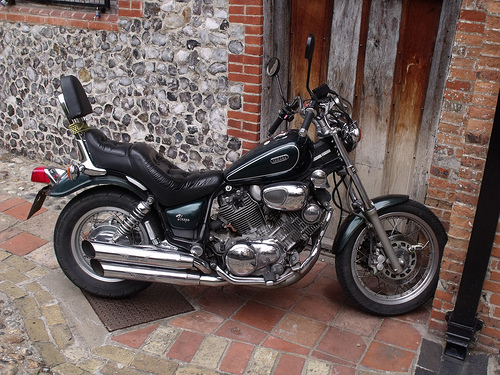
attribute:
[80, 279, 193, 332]
mat — black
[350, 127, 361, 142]
headlight — chrome, small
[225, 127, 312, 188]
gas tank — silver, black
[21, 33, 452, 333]
bike — black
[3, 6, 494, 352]
building — brick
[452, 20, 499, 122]
wall — rock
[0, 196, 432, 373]
ground — brick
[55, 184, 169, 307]
wheel — back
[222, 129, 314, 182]
fuel tank — motorcycle, large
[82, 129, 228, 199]
seat — cushioned, black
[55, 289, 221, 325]
mat — brown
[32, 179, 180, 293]
tire — a motorcycle tire, back tire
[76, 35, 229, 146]
wall — rock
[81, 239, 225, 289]
exhaust pipes — chrome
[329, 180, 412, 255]
fender — black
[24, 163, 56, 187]
light — red, a tail light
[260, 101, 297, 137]
handlebar — black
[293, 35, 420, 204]
door — wood, brown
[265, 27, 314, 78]
mirrors — side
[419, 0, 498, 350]
wall — brick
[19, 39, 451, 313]
motorcycle — parked